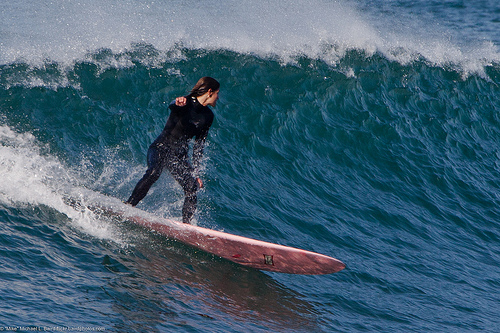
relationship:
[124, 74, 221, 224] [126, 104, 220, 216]
woman waring a wetsuit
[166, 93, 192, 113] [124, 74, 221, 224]
arm of woman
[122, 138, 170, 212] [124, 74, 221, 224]
leg of woman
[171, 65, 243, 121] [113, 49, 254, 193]
head of surfer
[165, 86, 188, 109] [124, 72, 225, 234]
hand of surfer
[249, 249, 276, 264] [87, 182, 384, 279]
logo on surfboard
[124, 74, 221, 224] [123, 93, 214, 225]
woman wearing wetsuit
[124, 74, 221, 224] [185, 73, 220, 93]
woman has hair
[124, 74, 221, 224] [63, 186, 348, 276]
woman standing on surfboard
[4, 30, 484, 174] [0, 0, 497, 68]
wave has crest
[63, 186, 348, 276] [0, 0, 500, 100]
surfboard for riding wave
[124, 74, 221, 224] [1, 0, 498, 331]
woman skating on water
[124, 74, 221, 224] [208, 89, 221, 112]
woman has face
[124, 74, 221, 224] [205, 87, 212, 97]
woman has ear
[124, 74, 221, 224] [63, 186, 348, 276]
woman standing in surfboard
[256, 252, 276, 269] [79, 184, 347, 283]
sticker under board